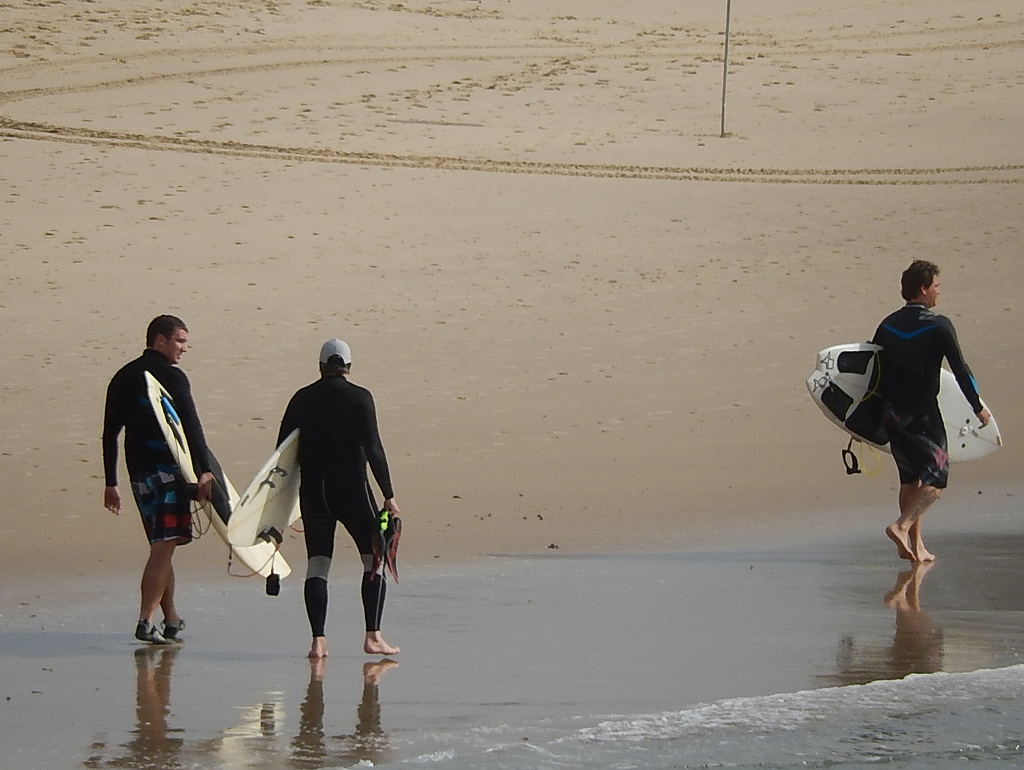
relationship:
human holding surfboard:
[805, 260, 1001, 561] [810, 338, 990, 462]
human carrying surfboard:
[99, 312, 291, 645] [132, 368, 293, 593]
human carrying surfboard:
[227, 335, 400, 664] [220, 430, 309, 565]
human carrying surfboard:
[805, 260, 1001, 561] [816, 337, 1013, 465]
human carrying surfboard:
[99, 312, 221, 652] [132, 368, 293, 593]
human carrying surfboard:
[227, 335, 400, 664] [222, 424, 303, 554]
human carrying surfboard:
[860, 253, 999, 576] [816, 337, 1013, 465]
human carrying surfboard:
[281, 335, 405, 675] [276, 331, 411, 669]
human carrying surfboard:
[99, 312, 221, 652] [136, 365, 288, 582]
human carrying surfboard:
[227, 335, 400, 664] [227, 426, 305, 558]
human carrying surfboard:
[227, 335, 400, 664] [220, 426, 300, 558]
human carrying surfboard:
[227, 335, 400, 664] [816, 337, 1013, 465]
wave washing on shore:
[371, 655, 1018, 759] [0, 0, 1024, 765]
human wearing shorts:
[227, 335, 400, 664] [121, 471, 193, 543]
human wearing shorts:
[860, 253, 999, 576] [877, 404, 951, 493]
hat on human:
[315, 335, 355, 374] [227, 335, 400, 664]